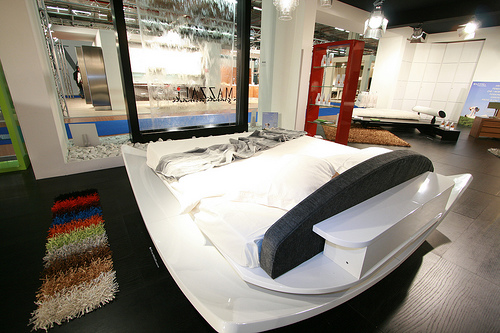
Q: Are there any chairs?
A: No, there are no chairs.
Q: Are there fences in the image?
A: No, there are no fences.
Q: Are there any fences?
A: No, there are no fences.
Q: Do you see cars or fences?
A: No, there are no fences or cars.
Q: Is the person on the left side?
A: Yes, the person is on the left of the image.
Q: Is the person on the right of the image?
A: No, the person is on the left of the image.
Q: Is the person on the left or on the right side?
A: The person is on the left of the image.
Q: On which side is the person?
A: The person is on the left of the image.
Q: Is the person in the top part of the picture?
A: Yes, the person is in the top of the image.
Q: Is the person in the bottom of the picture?
A: No, the person is in the top of the image.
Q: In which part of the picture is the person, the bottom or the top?
A: The person is in the top of the image.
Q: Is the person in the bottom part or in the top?
A: The person is in the top of the image.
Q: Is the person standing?
A: Yes, the person is standing.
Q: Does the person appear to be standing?
A: Yes, the person is standing.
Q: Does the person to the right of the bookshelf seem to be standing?
A: Yes, the person is standing.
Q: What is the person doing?
A: The person is standing.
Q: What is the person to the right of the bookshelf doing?
A: The person is standing.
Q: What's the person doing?
A: The person is standing.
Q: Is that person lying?
A: No, the person is standing.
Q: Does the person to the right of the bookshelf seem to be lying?
A: No, the person is standing.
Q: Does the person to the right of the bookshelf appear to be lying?
A: No, the person is standing.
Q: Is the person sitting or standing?
A: The person is standing.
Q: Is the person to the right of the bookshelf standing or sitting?
A: The person is standing.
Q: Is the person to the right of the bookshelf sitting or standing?
A: The person is standing.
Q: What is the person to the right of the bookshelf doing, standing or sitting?
A: The person is standing.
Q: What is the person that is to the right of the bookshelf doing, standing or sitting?
A: The person is standing.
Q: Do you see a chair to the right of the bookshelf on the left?
A: No, there is a person to the right of the bookshelf.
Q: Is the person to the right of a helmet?
A: No, the person is to the right of the bookshelf.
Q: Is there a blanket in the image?
A: Yes, there is a blanket.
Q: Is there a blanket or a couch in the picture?
A: Yes, there is a blanket.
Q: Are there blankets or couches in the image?
A: Yes, there is a blanket.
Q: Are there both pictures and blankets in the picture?
A: No, there is a blanket but no pictures.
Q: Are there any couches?
A: No, there are no couches.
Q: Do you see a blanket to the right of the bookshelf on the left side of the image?
A: Yes, there is a blanket to the right of the bookshelf.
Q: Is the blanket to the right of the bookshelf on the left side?
A: Yes, the blanket is to the right of the bookshelf.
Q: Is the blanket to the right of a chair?
A: No, the blanket is to the right of the bookshelf.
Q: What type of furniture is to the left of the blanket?
A: The piece of furniture is a bookshelf.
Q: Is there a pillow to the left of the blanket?
A: No, there is a bookshelf to the left of the blanket.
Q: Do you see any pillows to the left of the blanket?
A: No, there is a bookshelf to the left of the blanket.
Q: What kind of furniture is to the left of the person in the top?
A: The piece of furniture is a bookshelf.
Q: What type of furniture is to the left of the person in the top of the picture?
A: The piece of furniture is a bookshelf.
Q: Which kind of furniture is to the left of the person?
A: The piece of furniture is a bookshelf.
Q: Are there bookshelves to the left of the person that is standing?
A: Yes, there is a bookshelf to the left of the person.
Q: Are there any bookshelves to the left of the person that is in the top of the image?
A: Yes, there is a bookshelf to the left of the person.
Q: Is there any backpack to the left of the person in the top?
A: No, there is a bookshelf to the left of the person.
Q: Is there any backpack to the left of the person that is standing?
A: No, there is a bookshelf to the left of the person.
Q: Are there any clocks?
A: No, there are no clocks.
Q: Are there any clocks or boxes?
A: No, there are no clocks or boxes.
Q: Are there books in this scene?
A: No, there are no books.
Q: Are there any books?
A: No, there are no books.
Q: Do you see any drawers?
A: No, there are no drawers.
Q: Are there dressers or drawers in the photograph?
A: No, there are no drawers or dressers.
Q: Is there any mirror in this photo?
A: No, there are no mirrors.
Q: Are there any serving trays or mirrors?
A: No, there are no mirrors or serving trays.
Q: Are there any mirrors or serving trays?
A: No, there are no mirrors or serving trays.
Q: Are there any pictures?
A: No, there are no pictures.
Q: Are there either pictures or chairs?
A: No, there are no pictures or chairs.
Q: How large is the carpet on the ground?
A: The carpet is small.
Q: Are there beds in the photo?
A: Yes, there is a bed.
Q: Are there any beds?
A: Yes, there is a bed.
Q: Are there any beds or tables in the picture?
A: Yes, there is a bed.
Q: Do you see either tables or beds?
A: Yes, there is a bed.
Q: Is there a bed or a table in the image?
A: Yes, there is a bed.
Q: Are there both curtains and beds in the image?
A: No, there is a bed but no curtains.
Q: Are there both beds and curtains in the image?
A: No, there is a bed but no curtains.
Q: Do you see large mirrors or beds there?
A: Yes, there is a large bed.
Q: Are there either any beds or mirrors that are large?
A: Yes, the bed is large.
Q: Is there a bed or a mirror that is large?
A: Yes, the bed is large.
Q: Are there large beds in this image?
A: Yes, there is a large bed.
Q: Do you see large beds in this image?
A: Yes, there is a large bed.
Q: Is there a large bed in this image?
A: Yes, there is a large bed.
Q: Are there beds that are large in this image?
A: Yes, there is a large bed.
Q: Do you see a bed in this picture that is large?
A: Yes, there is a bed that is large.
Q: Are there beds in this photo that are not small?
A: Yes, there is a large bed.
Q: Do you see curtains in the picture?
A: No, there are no curtains.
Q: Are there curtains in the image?
A: No, there are no curtains.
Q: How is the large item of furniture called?
A: The piece of furniture is a bed.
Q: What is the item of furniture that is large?
A: The piece of furniture is a bed.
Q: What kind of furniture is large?
A: The furniture is a bed.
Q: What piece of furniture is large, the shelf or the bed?
A: The bed is large.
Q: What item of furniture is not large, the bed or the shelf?
A: The shelf is not large.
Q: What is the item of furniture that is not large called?
A: The piece of furniture is a shelf.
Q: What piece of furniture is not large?
A: The piece of furniture is a shelf.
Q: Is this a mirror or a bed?
A: This is a bed.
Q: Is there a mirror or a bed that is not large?
A: No, there is a bed but it is large.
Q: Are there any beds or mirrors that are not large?
A: No, there is a bed but it is large.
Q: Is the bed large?
A: Yes, the bed is large.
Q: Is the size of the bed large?
A: Yes, the bed is large.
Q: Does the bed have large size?
A: Yes, the bed is large.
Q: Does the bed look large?
A: Yes, the bed is large.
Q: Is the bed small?
A: No, the bed is large.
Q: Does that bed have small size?
A: No, the bed is large.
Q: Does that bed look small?
A: No, the bed is large.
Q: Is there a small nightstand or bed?
A: No, there is a bed but it is large.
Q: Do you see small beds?
A: No, there is a bed but it is large.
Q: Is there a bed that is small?
A: No, there is a bed but it is large.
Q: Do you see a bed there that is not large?
A: No, there is a bed but it is large.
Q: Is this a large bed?
A: Yes, this is a large bed.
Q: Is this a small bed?
A: No, this is a large bed.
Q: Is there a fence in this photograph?
A: No, there are no fences.